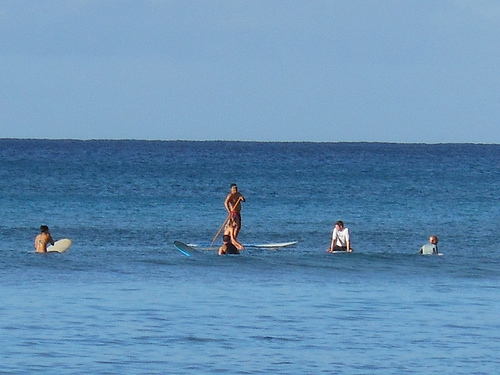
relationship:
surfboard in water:
[165, 232, 215, 265] [2, 138, 497, 373]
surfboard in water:
[44, 233, 87, 253] [78, 143, 495, 192]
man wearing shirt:
[325, 217, 354, 254] [328, 225, 350, 245]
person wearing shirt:
[414, 234, 446, 261] [417, 244, 437, 258]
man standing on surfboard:
[220, 180, 249, 252] [3, 147, 498, 364]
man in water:
[325, 217, 354, 254] [2, 138, 497, 373]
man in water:
[419, 234, 440, 257] [2, 138, 497, 373]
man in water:
[220, 180, 249, 252] [2, 138, 497, 373]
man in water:
[219, 233, 240, 259] [2, 138, 497, 373]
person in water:
[35, 221, 56, 254] [2, 138, 497, 373]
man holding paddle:
[220, 180, 249, 252] [215, 191, 272, 213]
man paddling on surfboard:
[220, 180, 249, 252] [181, 232, 297, 252]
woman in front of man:
[223, 216, 246, 251] [222, 180, 244, 241]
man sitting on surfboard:
[325, 217, 354, 254] [173, 237, 298, 258]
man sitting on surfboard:
[417, 234, 439, 256] [173, 237, 298, 258]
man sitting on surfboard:
[214, 232, 238, 260] [173, 237, 298, 258]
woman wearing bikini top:
[165, 172, 283, 288] [32, 237, 47, 245]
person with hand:
[35, 221, 52, 254] [45, 227, 53, 237]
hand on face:
[45, 227, 53, 237] [45, 226, 49, 235]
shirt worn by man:
[330, 227, 351, 251] [323, 219, 353, 241]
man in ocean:
[220, 180, 249, 252] [49, 140, 486, 342]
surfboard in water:
[180, 237, 304, 251] [2, 138, 497, 373]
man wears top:
[219, 233, 240, 259] [223, 242, 240, 256]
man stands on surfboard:
[220, 180, 249, 252] [183, 234, 301, 258]